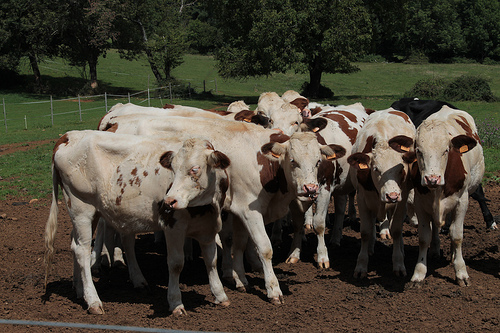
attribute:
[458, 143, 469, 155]
tag — orange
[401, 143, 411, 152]
tag — orange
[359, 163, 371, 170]
tag — orange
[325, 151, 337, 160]
tag — orange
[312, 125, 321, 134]
tag — orange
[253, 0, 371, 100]
tree — green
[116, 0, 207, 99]
tree — green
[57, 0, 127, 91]
tree — green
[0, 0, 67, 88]
tree — green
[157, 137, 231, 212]
cow face — white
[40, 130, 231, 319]
calve — brown, white, small, looking around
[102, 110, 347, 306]
calve — brown, white, small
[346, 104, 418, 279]
calve — brown, white, small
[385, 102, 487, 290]
calve — brown, white, small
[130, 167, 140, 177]
spot — brown, white, small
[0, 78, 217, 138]
fence — metal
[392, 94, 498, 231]
calve — black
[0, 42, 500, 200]
grass — green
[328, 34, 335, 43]
leaf — green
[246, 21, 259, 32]
leaf — green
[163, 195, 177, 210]
nose — pink